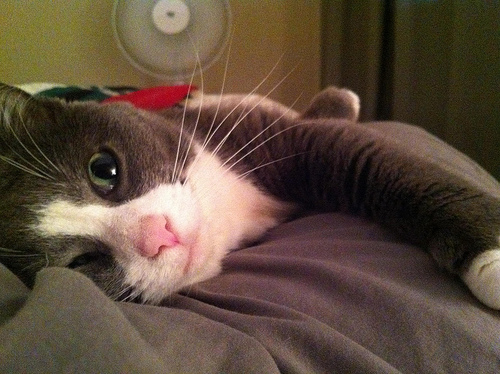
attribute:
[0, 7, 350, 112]
wall — beige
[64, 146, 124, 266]
eyes — green 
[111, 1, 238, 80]
fan — white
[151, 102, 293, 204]
whisker — white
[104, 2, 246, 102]
fan — white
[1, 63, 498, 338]
cat — grey and white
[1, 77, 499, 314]
cat — grey and white, pink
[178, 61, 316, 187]
whiskers — white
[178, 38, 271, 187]
whisker — white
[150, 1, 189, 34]
white circle — small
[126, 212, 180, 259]
nose — pink 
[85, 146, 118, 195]
eye — green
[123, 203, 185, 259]
nose — pink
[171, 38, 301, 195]
whisker — white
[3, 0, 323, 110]
wall — yellow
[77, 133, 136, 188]
eyes — green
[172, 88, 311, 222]
hair — white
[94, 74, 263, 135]
pillow — red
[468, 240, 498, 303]
paw — white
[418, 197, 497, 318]
paw — grey and white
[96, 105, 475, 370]
blanket — grey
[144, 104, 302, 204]
whiskers — white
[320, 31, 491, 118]
curtain — green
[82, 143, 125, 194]
eye — open